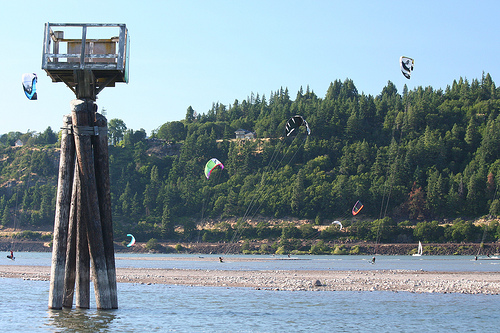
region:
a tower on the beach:
[40, 21, 132, 312]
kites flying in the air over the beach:
[20, 55, 415, 247]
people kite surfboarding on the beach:
[202, 56, 414, 265]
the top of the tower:
[41, 21, 132, 100]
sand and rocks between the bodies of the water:
[274, 268, 497, 291]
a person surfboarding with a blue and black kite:
[2, 73, 41, 260]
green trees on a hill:
[313, 70, 498, 198]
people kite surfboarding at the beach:
[1, 54, 498, 266]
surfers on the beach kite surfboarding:
[195, 53, 416, 268]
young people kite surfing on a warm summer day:
[189, 53, 428, 268]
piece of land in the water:
[1, 259, 498, 300]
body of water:
[1, 246, 498, 331]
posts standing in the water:
[47, 97, 124, 315]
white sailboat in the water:
[410, 238, 425, 260]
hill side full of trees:
[1, 76, 499, 261]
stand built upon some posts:
[38, 18, 134, 101]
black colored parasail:
[278, 112, 319, 142]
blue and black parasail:
[20, 65, 43, 107]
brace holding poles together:
[58, 121, 110, 141]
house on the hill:
[230, 121, 260, 143]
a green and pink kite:
[200, 151, 230, 184]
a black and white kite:
[276, 112, 320, 142]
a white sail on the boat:
[412, 238, 429, 256]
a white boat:
[408, 249, 426, 259]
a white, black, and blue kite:
[16, 68, 48, 103]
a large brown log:
[71, 98, 116, 313]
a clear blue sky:
[0, 0, 497, 133]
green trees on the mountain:
[0, 67, 499, 248]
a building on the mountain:
[233, 118, 263, 142]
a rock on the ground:
[309, 277, 321, 287]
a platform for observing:
[40, 21, 127, 79]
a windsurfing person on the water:
[411, 239, 423, 260]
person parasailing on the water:
[367, 254, 379, 265]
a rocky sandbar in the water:
[114, 264, 499, 294]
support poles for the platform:
[47, 107, 117, 312]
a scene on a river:
[0, 1, 497, 330]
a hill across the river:
[0, 77, 499, 258]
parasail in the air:
[201, 154, 225, 179]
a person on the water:
[216, 253, 226, 265]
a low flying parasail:
[125, 229, 136, 250]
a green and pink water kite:
[200, 154, 228, 181]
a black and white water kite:
[276, 109, 315, 140]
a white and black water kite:
[396, 54, 418, 82]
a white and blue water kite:
[20, 68, 40, 103]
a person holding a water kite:
[216, 247, 226, 268]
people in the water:
[0, 247, 495, 328]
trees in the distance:
[1, 67, 491, 252]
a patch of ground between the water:
[0, 261, 498, 296]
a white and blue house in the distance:
[231, 126, 254, 137]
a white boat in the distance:
[408, 241, 427, 258]